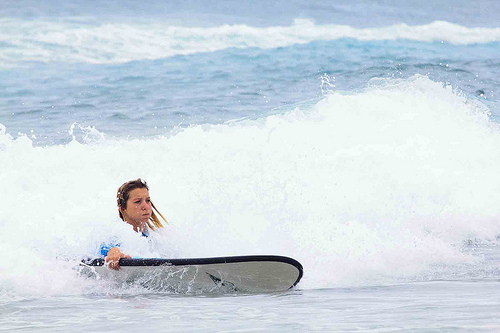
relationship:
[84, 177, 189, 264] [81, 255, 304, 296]
woman on top of surfboard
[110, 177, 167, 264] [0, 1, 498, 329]
woman in water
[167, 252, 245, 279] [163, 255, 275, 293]
black ring around surfboard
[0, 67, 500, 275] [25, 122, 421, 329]
wave of water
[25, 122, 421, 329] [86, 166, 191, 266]
water behind woman